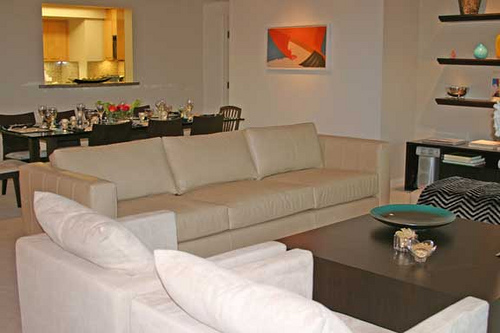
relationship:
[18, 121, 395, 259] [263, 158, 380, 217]
sofa with cushion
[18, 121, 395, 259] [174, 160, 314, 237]
sofa with cushion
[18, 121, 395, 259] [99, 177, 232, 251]
sofa with cushion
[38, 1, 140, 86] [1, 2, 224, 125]
window in wall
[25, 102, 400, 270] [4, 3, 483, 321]
sofa in room